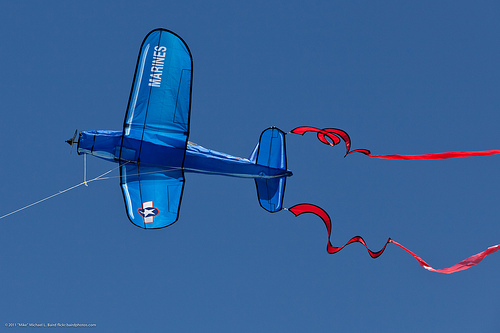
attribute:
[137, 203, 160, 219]
star — white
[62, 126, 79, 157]
propeller — black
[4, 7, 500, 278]
kite — the sky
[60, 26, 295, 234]
kite — airplane